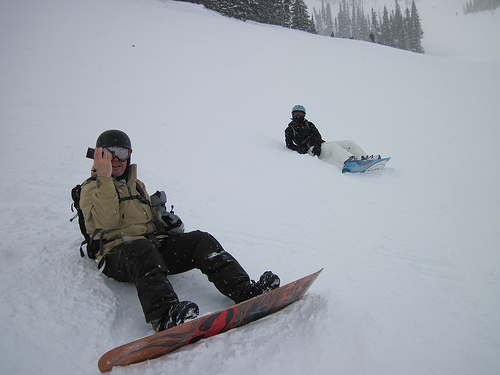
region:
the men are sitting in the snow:
[60, 80, 412, 363]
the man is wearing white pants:
[316, 136, 368, 168]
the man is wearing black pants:
[98, 222, 254, 329]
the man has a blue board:
[336, 152, 394, 185]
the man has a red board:
[85, 258, 330, 373]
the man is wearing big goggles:
[93, 143, 134, 173]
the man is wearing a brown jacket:
[65, 157, 180, 272]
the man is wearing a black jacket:
[281, 110, 325, 158]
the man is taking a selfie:
[67, 120, 282, 333]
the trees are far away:
[153, 0, 430, 59]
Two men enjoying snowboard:
[45, 86, 445, 371]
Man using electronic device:
[55, 125, 285, 370]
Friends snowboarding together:
[51, 90, 411, 370]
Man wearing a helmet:
[72, 120, 157, 175]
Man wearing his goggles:
[77, 126, 147, 181]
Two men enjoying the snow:
[55, 70, 440, 370]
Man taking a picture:
[60, 121, 157, 186]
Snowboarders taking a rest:
[55, 70, 420, 370]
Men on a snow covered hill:
[55, 70, 410, 370]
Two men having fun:
[58, 93, 429, 370]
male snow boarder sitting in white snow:
[13, 112, 239, 299]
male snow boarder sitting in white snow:
[271, 76, 398, 204]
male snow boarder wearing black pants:
[113, 245, 229, 295]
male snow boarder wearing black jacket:
[284, 127, 314, 142]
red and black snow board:
[207, 305, 262, 335]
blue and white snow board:
[342, 160, 390, 185]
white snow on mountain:
[11, 187, 75, 323]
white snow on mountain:
[335, 203, 450, 328]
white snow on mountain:
[50, 18, 217, 92]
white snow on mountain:
[191, 41, 323, 87]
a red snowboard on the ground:
[90, 254, 329, 366]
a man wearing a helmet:
[60, 119, 157, 184]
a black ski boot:
[125, 289, 215, 327]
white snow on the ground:
[332, 202, 437, 314]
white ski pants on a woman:
[314, 122, 384, 172]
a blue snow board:
[327, 138, 407, 178]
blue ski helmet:
[282, 96, 312, 121]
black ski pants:
[95, 192, 263, 324]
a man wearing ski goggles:
[92, 140, 143, 160]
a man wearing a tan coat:
[54, 157, 194, 242]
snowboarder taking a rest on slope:
[72, 101, 278, 261]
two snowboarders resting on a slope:
[95, 85, 411, 215]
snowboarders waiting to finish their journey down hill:
[41, 71, 417, 191]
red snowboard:
[117, 310, 342, 341]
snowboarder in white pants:
[268, 95, 384, 180]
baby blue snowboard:
[330, 157, 446, 187]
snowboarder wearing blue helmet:
[292, 104, 319, 122]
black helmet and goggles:
[29, 123, 151, 155]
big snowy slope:
[76, 7, 241, 142]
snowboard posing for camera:
[288, 89, 375, 174]